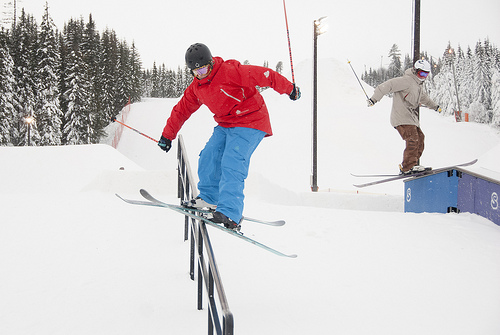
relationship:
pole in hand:
[283, 1, 297, 84] [290, 84, 302, 101]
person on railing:
[156, 42, 301, 231] [177, 133, 234, 335]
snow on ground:
[2, 80, 498, 334] [2, 98, 498, 334]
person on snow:
[156, 42, 301, 231] [2, 80, 498, 334]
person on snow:
[368, 57, 443, 177] [2, 80, 498, 334]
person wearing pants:
[156, 42, 301, 231] [199, 124, 268, 225]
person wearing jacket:
[156, 42, 301, 231] [161, 57, 295, 140]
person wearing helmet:
[156, 42, 301, 231] [184, 43, 213, 75]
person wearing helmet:
[368, 57, 443, 177] [413, 58, 431, 74]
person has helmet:
[156, 42, 301, 231] [184, 43, 213, 75]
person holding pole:
[156, 42, 301, 231] [283, 1, 297, 84]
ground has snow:
[2, 98, 498, 334] [2, 80, 498, 334]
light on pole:
[313, 16, 325, 38] [312, 19, 318, 190]